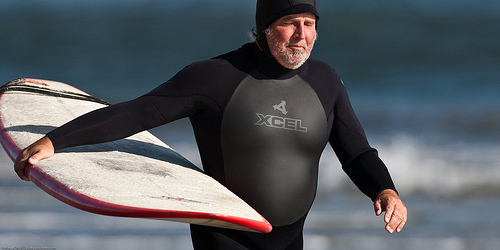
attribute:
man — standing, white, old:
[205, 4, 398, 248]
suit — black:
[235, 87, 319, 192]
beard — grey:
[268, 38, 317, 70]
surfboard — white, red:
[6, 76, 220, 223]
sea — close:
[380, 34, 429, 85]